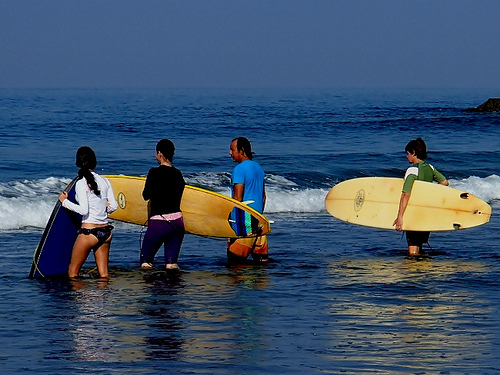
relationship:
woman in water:
[53, 143, 121, 288] [1, 100, 500, 374]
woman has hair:
[53, 143, 121, 288] [72, 145, 104, 200]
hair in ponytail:
[72, 145, 104, 200] [76, 165, 100, 197]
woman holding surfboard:
[53, 143, 121, 288] [28, 173, 77, 282]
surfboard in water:
[28, 173, 77, 282] [1, 100, 500, 374]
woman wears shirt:
[53, 143, 121, 288] [58, 170, 122, 226]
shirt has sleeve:
[58, 170, 122, 226] [101, 177, 122, 217]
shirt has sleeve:
[58, 170, 122, 226] [61, 180, 93, 217]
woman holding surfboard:
[134, 136, 190, 273] [82, 173, 275, 245]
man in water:
[222, 133, 274, 267] [1, 100, 500, 374]